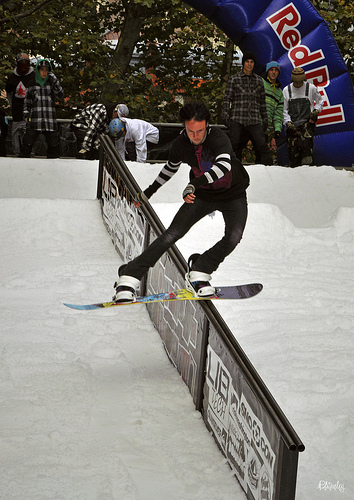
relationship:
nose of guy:
[189, 129, 202, 146] [112, 101, 250, 304]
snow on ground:
[0, 199, 100, 273] [2, 158, 348, 337]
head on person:
[177, 102, 212, 149] [111, 88, 258, 324]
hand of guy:
[183, 182, 196, 205] [112, 101, 250, 304]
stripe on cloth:
[204, 169, 213, 184] [211, 135, 231, 171]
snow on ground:
[2, 158, 350, 498] [0, 159, 349, 495]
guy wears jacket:
[22, 58, 64, 158] [20, 70, 65, 133]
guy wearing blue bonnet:
[260, 61, 284, 166] [265, 61, 280, 71]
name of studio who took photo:
[312, 475, 352, 497] [51, 185, 324, 435]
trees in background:
[3, 2, 110, 99] [6, 1, 343, 62]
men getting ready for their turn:
[230, 55, 317, 165] [74, 206, 278, 370]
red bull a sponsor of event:
[240, 3, 348, 112] [29, 187, 304, 378]